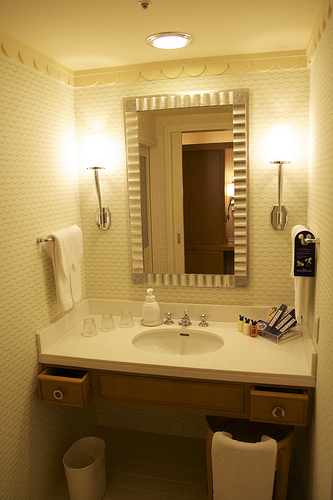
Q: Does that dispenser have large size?
A: Yes, the dispenser is large.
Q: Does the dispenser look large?
A: Yes, the dispenser is large.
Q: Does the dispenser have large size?
A: Yes, the dispenser is large.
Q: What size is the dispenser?
A: The dispenser is large.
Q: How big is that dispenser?
A: The dispenser is large.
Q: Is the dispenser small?
A: No, the dispenser is large.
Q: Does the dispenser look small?
A: No, the dispenser is large.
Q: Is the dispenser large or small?
A: The dispenser is large.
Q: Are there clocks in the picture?
A: No, there are no clocks.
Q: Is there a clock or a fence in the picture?
A: No, there are no clocks or fences.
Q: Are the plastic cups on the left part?
A: Yes, the cups are on the left of the image.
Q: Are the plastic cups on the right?
A: No, the cups are on the left of the image.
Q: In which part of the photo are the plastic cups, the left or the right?
A: The cups are on the left of the image.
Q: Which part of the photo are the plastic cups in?
A: The cups are on the left of the image.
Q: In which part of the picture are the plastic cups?
A: The cups are on the left of the image.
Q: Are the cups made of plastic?
A: Yes, the cups are made of plastic.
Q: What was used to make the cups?
A: The cups are made of plastic.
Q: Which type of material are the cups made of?
A: The cups are made of plastic.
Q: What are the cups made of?
A: The cups are made of plastic.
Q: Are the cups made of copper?
A: No, the cups are made of plastic.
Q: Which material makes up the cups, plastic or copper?
A: The cups are made of plastic.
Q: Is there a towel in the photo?
A: Yes, there is a towel.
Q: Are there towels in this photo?
A: Yes, there is a towel.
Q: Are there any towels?
A: Yes, there is a towel.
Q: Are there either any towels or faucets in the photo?
A: Yes, there is a towel.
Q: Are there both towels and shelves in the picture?
A: No, there is a towel but no shelves.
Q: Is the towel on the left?
A: Yes, the towel is on the left of the image.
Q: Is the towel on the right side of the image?
A: No, the towel is on the left of the image.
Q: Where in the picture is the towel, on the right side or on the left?
A: The towel is on the left of the image.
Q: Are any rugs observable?
A: No, there are no rugs.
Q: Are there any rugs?
A: No, there are no rugs.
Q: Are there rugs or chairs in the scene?
A: No, there are no rugs or chairs.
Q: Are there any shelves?
A: No, there are no shelves.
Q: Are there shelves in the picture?
A: No, there are no shelves.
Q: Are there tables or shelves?
A: No, there are no shelves or tables.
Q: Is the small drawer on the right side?
A: Yes, the drawer is on the right of the image.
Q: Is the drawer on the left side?
A: No, the drawer is on the right of the image.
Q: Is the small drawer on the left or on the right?
A: The drawer is on the right of the image.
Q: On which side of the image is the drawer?
A: The drawer is on the right of the image.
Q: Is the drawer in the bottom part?
A: Yes, the drawer is in the bottom of the image.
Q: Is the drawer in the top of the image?
A: No, the drawer is in the bottom of the image.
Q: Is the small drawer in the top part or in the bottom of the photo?
A: The drawer is in the bottom of the image.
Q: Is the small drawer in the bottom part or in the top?
A: The drawer is in the bottom of the image.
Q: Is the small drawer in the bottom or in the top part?
A: The drawer is in the bottom of the image.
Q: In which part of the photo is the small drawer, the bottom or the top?
A: The drawer is in the bottom of the image.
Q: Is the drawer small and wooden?
A: Yes, the drawer is small and wooden.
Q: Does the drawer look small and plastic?
A: No, the drawer is small but wooden.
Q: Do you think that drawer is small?
A: Yes, the drawer is small.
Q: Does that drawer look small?
A: Yes, the drawer is small.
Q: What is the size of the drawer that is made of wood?
A: The drawer is small.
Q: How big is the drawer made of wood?
A: The drawer is small.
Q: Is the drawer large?
A: No, the drawer is small.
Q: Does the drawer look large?
A: No, the drawer is small.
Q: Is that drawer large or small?
A: The drawer is small.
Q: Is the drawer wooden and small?
A: Yes, the drawer is wooden and small.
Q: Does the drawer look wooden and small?
A: Yes, the drawer is wooden and small.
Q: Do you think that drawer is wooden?
A: Yes, the drawer is wooden.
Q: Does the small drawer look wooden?
A: Yes, the drawer is wooden.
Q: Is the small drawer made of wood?
A: Yes, the drawer is made of wood.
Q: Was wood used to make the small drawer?
A: Yes, the drawer is made of wood.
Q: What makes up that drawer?
A: The drawer is made of wood.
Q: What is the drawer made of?
A: The drawer is made of wood.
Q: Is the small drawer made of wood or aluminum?
A: The drawer is made of wood.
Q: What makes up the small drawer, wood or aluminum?
A: The drawer is made of wood.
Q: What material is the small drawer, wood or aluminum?
A: The drawer is made of wood.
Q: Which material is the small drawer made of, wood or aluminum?
A: The drawer is made of wood.